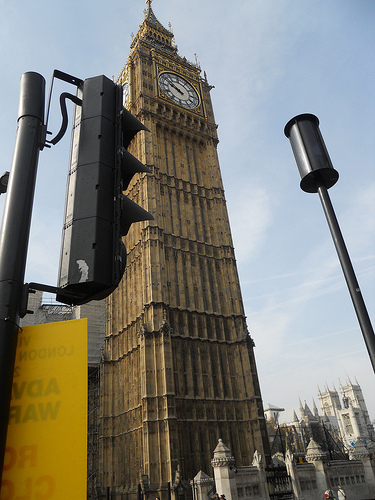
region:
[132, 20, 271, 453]
clock tower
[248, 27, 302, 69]
white clouds in blue sky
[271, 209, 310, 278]
white clouds in blue sky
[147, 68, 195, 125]
clock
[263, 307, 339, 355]
white clouds in blue sky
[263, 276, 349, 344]
white clouds in blue sky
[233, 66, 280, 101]
white clouds in blue sky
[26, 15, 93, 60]
white clouds in blue sky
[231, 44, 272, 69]
white clouds in blue sky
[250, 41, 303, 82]
white clouds in blue sky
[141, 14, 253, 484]
brown clock tower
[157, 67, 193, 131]
black and white clock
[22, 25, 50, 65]
white clouds in blue sky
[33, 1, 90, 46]
white clouds in blue sky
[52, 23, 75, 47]
white clouds in blue sky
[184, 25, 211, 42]
white clouds in blue sky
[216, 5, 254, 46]
white clouds in blue sky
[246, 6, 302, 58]
white clouds in blue sky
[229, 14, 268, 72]
white clouds in blue sky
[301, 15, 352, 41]
white clouds in blue sky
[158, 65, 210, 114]
clock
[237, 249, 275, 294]
white clouds in blue sky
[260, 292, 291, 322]
white clouds in blue sky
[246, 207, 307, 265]
white clouds in blue sky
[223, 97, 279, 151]
white clouds in blue sky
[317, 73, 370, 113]
white clouds in blue sky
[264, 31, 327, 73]
white clouds in blue sky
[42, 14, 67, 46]
white clouds in blue sky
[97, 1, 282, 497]
a very large tower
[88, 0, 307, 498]
this tower is known as Big Ben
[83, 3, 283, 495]
this tower is in London, England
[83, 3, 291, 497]
this tower has a large clock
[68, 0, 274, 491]
a very large clock tower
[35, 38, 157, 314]
a street stop light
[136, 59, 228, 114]
the clock has a white face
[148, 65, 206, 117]
the clock features Roman numerals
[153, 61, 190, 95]
the minute and hour hands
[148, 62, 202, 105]
the hands of the clock are black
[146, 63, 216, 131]
white clock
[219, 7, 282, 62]
white clouds n blue sky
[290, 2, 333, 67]
white clouds n blue sky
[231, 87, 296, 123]
white clouds n blue sky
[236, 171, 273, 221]
white clouds n blue sky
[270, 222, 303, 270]
white clouds n blue sky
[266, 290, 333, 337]
white clouds n blue sky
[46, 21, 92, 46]
white clouds n blue sky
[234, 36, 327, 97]
white clouds n blue sky